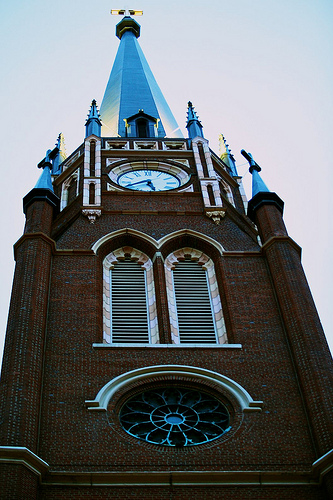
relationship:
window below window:
[85, 364, 264, 447] [101, 248, 151, 346]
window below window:
[85, 364, 264, 447] [170, 251, 218, 343]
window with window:
[91, 227, 242, 348] [91, 227, 242, 348]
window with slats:
[91, 227, 242, 348] [113, 257, 147, 340]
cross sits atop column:
[239, 144, 268, 173] [249, 168, 270, 197]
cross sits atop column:
[240, 149, 262, 174] [0, 184, 62, 498]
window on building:
[97, 245, 161, 347] [1, 7, 332, 497]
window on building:
[91, 227, 242, 348] [1, 7, 332, 497]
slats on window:
[176, 270, 203, 320] [161, 237, 208, 348]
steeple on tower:
[99, 9, 185, 139] [0, 10, 332, 497]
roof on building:
[26, 6, 274, 195] [1, 7, 332, 497]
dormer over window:
[93, 226, 155, 255] [101, 248, 158, 346]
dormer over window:
[90, 227, 226, 252] [165, 246, 223, 344]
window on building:
[112, 374, 240, 450] [1, 7, 332, 497]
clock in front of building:
[101, 153, 198, 202] [0, 9, 333, 500]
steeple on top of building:
[97, 5, 186, 141] [1, 7, 332, 497]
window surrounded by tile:
[61, 179, 87, 205] [163, 246, 228, 347]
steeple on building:
[99, 9, 185, 139] [11, 39, 255, 337]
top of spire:
[108, 6, 146, 13] [106, 5, 146, 38]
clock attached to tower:
[103, 160, 195, 191] [19, 50, 296, 379]